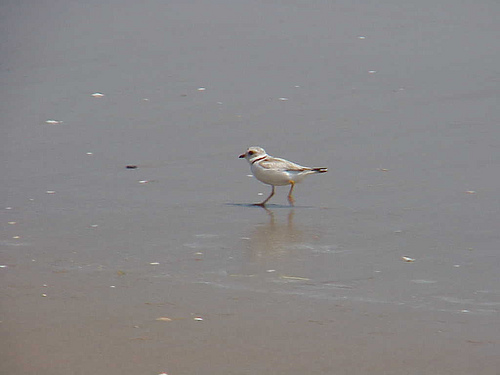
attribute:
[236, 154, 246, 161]
beak — black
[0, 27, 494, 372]
sand — wet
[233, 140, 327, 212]
bird — walking in dirt, black 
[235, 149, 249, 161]
beak — black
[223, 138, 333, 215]
bird — walking 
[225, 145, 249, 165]
beak — black 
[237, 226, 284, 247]
sand — wet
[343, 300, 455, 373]
sand — wet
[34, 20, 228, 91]
clouds — white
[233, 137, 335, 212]
bird — white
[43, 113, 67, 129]
seashells — white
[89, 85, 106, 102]
seashells — white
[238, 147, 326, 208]
bird — walking in dirt, grey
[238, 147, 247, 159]
beak — black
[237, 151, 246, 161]
beak — black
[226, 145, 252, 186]
beak — black 